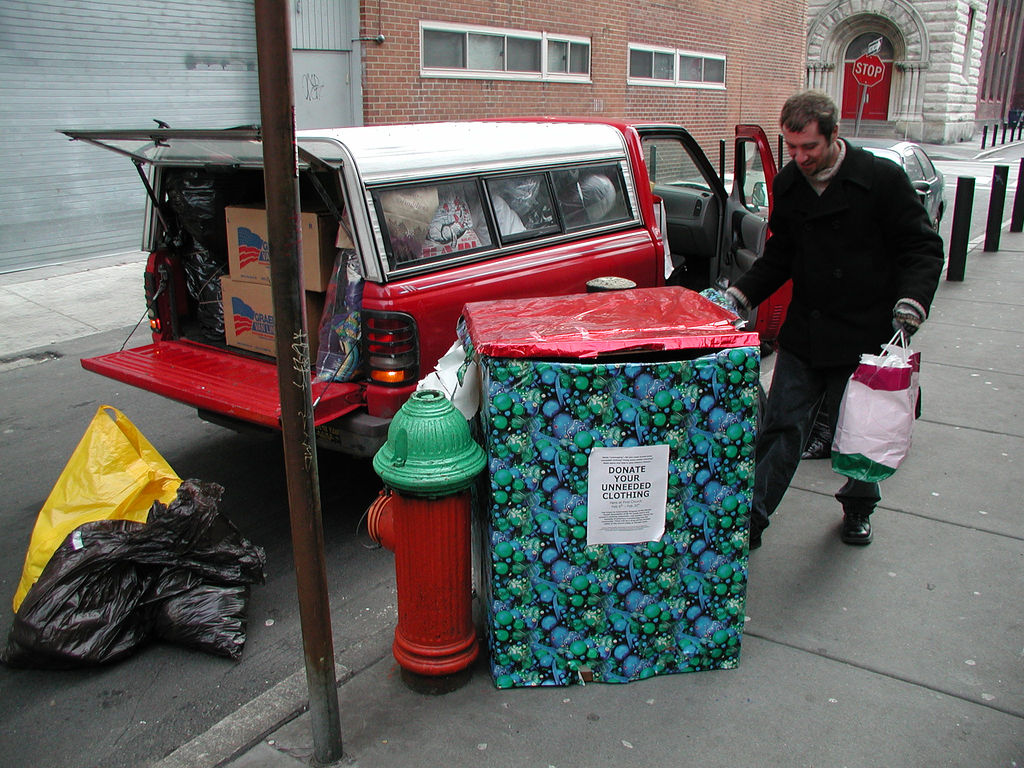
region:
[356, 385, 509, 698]
Red fire hydrant with green top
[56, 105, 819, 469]
Red truck with it's back door open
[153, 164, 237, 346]
Black bags packed into the back of a truck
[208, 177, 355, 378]
Boxes packed into the back of a truck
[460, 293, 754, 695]
Box for collection of clothing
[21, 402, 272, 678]
Black and yellow trash bags in a pile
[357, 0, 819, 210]
Brick building with windows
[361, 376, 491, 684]
red and green fire hydrant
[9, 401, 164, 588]
yellow plastic bag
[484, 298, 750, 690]
wrapped cardboard box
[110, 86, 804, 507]
red truck with camper shell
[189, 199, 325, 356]
boxes in the truck bed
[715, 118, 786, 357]
open door of the truck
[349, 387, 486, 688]
the fire hydrant is red and green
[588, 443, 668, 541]
the white paper with black letters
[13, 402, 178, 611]
the large plastic yellow bag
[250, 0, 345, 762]
the pole is tall and brown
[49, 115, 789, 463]
the vehicle is red and white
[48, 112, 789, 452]
the opened doors on the red and white vehicle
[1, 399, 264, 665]
the black bags next to the yellow bag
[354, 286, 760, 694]
the colorful box next to the fire hydrant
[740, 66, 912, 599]
man wearing a black coat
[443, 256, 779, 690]
large box with wrapping paper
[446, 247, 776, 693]
box with red top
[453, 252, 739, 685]
box for clothing donations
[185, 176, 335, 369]
boxes in the back of the truck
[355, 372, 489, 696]
red fire hydrant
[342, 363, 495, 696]
top of hydrant is green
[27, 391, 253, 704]
yellow and black trash bags in the street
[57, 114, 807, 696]
A red pickup truck parked in front of a fire hydrant.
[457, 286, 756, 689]
A clothing donation box covered in blue and green paper with a red lid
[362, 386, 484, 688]
a red fire hydrant with a green top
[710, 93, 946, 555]
a man in a black coat carrying a shopping bag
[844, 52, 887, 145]
a red stop sign in the background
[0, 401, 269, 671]
two plastic bags, one yellow and one black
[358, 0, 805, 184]
several windows in a wall of brick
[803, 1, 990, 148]
a red door in a white stone building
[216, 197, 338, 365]
American flags printed on two brown cardboard boxes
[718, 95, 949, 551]
a man looking at his feet and smiling